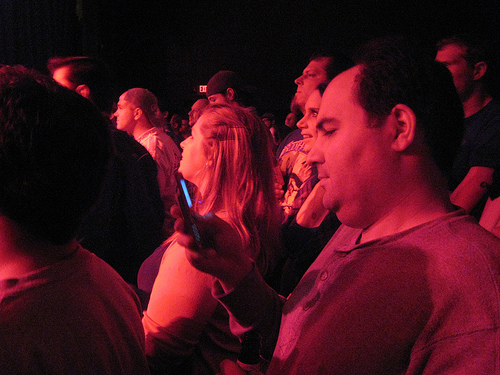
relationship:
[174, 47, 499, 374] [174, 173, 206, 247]
man looks at phone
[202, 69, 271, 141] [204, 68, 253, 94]
man has cap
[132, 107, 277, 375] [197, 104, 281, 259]
woman has hair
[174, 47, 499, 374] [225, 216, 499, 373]
man wears shirt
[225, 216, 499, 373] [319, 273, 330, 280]
shirt has button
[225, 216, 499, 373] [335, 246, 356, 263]
shirt has button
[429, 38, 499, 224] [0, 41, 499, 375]
person in group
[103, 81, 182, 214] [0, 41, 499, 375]
person in group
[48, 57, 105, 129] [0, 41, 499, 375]
person in group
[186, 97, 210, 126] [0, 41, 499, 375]
person in group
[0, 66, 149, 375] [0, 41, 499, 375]
person in group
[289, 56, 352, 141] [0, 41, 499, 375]
person in group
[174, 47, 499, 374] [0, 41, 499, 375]
man in group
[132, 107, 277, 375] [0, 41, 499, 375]
woman in group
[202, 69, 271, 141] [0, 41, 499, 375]
man in group